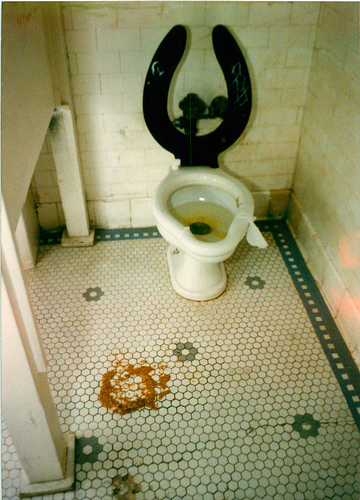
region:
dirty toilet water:
[172, 196, 233, 245]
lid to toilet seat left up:
[142, 20, 255, 159]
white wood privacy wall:
[0, 2, 91, 495]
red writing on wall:
[4, 0, 42, 28]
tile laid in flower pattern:
[74, 271, 318, 447]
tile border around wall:
[37, 217, 357, 430]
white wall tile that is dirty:
[31, 5, 358, 353]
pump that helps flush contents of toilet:
[171, 84, 225, 138]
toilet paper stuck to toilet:
[235, 193, 265, 251]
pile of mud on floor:
[99, 352, 171, 410]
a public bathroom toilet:
[67, 5, 344, 431]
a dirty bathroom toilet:
[121, 8, 298, 317]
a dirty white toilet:
[117, 4, 291, 314]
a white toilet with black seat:
[100, 11, 308, 366]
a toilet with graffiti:
[137, 44, 302, 328]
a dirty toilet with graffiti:
[108, 5, 323, 360]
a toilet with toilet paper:
[129, 152, 270, 313]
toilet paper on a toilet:
[134, 171, 294, 334]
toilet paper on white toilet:
[155, 158, 265, 355]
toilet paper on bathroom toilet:
[144, 165, 273, 329]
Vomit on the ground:
[100, 358, 166, 413]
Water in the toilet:
[172, 198, 233, 240]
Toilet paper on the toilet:
[235, 208, 265, 245]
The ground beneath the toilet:
[0, 245, 358, 498]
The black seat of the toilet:
[143, 22, 253, 165]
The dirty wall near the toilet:
[60, 2, 359, 366]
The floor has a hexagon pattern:
[32, 235, 359, 496]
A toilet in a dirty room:
[142, 24, 256, 298]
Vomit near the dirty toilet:
[99, 358, 168, 414]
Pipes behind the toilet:
[179, 96, 225, 134]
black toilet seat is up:
[146, 32, 250, 155]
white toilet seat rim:
[148, 186, 240, 274]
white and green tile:
[231, 305, 306, 409]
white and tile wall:
[265, 37, 288, 168]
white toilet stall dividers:
[35, 70, 104, 277]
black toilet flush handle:
[145, 75, 245, 163]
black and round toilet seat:
[136, 39, 247, 168]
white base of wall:
[291, 186, 357, 361]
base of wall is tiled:
[280, 190, 359, 334]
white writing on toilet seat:
[137, 41, 254, 117]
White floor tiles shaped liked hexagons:
[0, 230, 358, 498]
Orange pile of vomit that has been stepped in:
[96, 349, 182, 415]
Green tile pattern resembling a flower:
[290, 411, 321, 440]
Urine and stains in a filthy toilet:
[165, 197, 234, 242]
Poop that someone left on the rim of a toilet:
[232, 194, 242, 211]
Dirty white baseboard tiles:
[36, 187, 359, 372]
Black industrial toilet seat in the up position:
[140, 22, 253, 169]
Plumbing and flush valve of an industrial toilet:
[169, 92, 228, 136]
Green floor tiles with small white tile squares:
[37, 216, 358, 427]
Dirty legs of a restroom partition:
[0, 104, 97, 497]